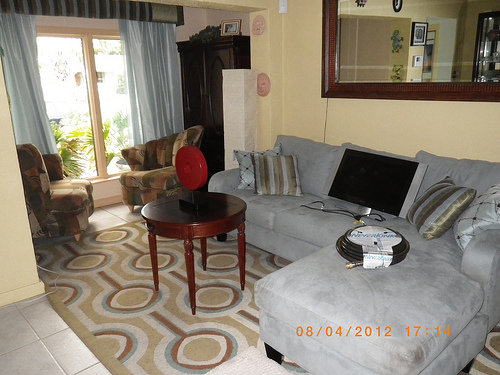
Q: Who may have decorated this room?
A: Interior designer.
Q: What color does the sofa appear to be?
A: Light gray.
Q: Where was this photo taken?
A: Living room.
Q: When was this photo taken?
A: Daytime.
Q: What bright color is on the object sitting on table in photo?
A: Red.